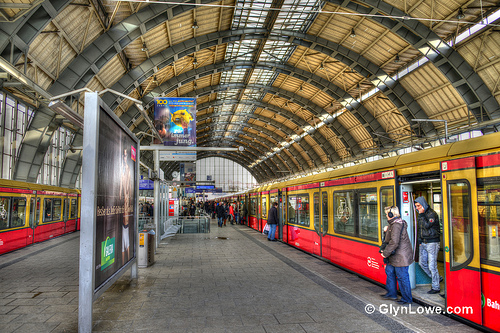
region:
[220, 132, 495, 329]
yellow and red train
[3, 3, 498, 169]
train station has a domed ceiling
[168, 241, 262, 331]
floor of station is grey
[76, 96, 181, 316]
large signs set up in the center of train station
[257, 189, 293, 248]
person facing train's interior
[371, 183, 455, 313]
people leaving train car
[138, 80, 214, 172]
colorful sign hung near ceiling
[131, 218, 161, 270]
trash receptacle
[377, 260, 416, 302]
person wearing blue pants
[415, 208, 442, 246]
man wearing black jacket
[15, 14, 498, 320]
Train station stop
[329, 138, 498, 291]
Men exiting from train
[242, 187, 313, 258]
Man entering train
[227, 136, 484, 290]
Train is red and gold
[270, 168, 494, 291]
Train has black trimming around windows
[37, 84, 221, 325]
the train station has several billboard advertisments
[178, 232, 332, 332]
The walkway is comprised of cement bricks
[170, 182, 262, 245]
People walking alongside the train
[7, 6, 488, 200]
Arched ceiling with ceiling windows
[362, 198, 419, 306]
Man wearing headphones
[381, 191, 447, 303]
Two people leaving train.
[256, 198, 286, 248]
One person getting on train.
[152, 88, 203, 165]
Ad sign hanging from ceiling.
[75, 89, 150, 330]
Bill board sign standing on floor of train terminal.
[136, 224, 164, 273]
Trash can sitting on floor of train terminal.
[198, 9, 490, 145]
Girders mounted on ceiling of train terminal.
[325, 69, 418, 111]
Lights mounted on ceiling of train station.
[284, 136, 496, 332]
A red and yellow train.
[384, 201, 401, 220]
A person wearing headphones.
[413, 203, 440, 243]
Person wearing black leather jacket.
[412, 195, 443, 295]
man getting off train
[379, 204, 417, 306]
woman who just got off train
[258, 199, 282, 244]
man preparing to get on train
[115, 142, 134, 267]
underwear model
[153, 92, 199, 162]
movie poster is hanging high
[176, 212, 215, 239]
stairs that lead to a lower level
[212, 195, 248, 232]
people milling about in a train station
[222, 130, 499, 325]
a long red and yellow passenger train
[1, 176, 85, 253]
another red and yellow train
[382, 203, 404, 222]
earphones on a woman's head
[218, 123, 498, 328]
A red and yellow train in a station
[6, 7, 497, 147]
the high domed ceiling at the train station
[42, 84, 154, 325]
large sign for advertising on the platform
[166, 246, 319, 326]
grey bricks the platform is made of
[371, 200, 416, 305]
a woman in a brown jacket exiting the train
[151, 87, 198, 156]
an advertisement sign hanging high above the platform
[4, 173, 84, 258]
a red and yellow train on the other set of tracks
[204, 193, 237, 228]
people in the distance walking on the platform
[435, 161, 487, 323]
a sliding door on the train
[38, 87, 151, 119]
light fixtures on the sign